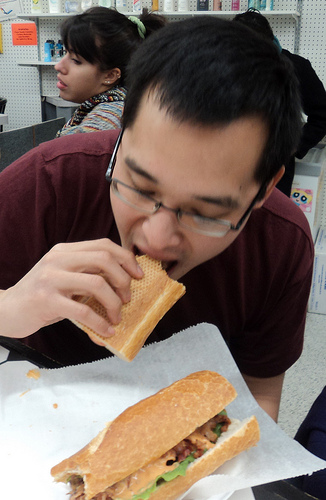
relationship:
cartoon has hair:
[286, 186, 318, 216] [291, 185, 315, 201]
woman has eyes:
[38, 2, 171, 140] [58, 48, 85, 69]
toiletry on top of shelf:
[44, 37, 60, 65] [12, 56, 61, 73]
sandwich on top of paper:
[63, 252, 194, 367] [3, 318, 325, 499]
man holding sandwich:
[0, 17, 322, 498] [63, 252, 194, 367]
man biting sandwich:
[0, 17, 322, 498] [63, 252, 194, 367]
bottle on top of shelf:
[258, 0, 277, 13] [15, 8, 303, 23]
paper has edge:
[3, 318, 325, 499] [0, 316, 213, 382]